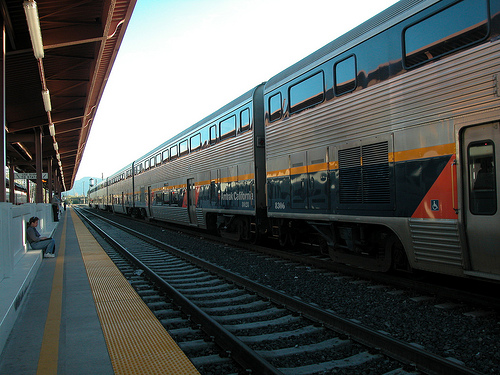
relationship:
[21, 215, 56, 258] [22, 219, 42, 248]
man on bench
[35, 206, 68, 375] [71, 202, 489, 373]
line by tracks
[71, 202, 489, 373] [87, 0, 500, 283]
tracks for a amtrak train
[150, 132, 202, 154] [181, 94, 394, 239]
windows of a train car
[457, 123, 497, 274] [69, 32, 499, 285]
door on train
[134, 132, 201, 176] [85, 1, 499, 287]
windows on side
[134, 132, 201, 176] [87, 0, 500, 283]
windows on amtrak train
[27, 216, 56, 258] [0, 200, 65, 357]
man on bench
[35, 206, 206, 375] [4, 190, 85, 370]
paint on platform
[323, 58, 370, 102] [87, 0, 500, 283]
window on amtrak train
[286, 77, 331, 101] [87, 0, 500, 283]
window on amtrak train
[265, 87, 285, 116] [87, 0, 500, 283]
window on amtrak train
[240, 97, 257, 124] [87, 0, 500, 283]
window on amtrak train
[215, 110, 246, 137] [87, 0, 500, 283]
window on amtrak train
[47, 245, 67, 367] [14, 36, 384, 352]
line on platform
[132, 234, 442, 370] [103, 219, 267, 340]
gravel around tracks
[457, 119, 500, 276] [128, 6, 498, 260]
door on train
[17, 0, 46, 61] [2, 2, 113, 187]
light on roof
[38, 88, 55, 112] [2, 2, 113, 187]
light on roof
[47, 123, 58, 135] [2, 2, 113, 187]
light on roof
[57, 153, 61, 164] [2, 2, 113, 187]
light on roof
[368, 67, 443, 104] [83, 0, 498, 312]
silver ridges on train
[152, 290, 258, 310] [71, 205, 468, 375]
tie on track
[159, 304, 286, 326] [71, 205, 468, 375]
tie on track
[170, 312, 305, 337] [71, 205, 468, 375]
tie on track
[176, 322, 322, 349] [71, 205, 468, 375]
tie on track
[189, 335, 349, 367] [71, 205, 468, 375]
tie on track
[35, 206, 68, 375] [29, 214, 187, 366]
line on platform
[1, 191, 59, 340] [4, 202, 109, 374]
bench on platform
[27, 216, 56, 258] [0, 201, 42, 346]
man on bench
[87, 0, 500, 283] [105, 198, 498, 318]
amtrak train on tracks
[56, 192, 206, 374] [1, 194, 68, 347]
paint on platform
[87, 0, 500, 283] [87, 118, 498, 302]
amtrak train has floor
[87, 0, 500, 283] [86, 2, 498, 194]
amtrak train has floor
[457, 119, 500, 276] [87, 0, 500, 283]
door of amtrak train